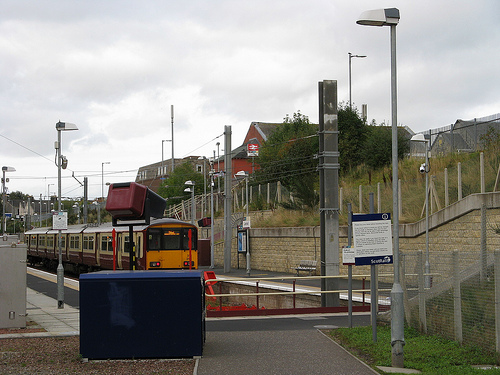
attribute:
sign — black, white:
[350, 212, 394, 266]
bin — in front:
[69, 261, 231, 369]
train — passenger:
[38, 224, 201, 280]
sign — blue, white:
[325, 210, 457, 273]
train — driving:
[15, 217, 200, 279]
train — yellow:
[16, 213, 200, 274]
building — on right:
[229, 116, 420, 180]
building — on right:
[412, 117, 498, 144]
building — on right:
[128, 157, 209, 202]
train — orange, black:
[5, 217, 199, 285]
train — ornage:
[18, 150, 240, 313]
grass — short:
[330, 324, 495, 370]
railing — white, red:
[206, 273, 389, 316]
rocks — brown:
[0, 328, 193, 373]